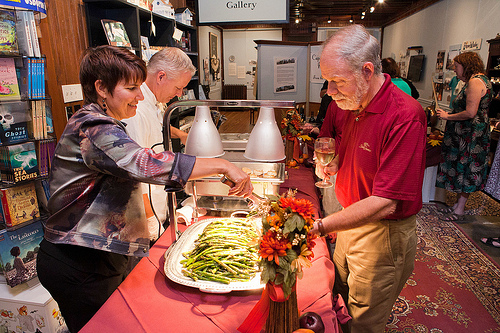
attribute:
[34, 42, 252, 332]
person — serving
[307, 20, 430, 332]
man — drinking, older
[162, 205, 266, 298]
plate — silver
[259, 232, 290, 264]
flower — orange, artificial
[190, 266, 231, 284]
asparagus — green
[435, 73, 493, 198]
dress — black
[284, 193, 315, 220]
flower — orange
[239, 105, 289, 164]
lamp — heated, silver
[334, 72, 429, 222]
shirt — red, collared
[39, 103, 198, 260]
jacket — printed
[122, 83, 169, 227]
shirt — white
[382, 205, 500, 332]
carpet — oriental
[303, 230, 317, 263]
flower — orange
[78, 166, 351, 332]
table cloth — red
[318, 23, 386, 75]
hair — thinning, grey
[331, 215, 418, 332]
pants — khaki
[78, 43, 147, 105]
hair — short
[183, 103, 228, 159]
lamp — heated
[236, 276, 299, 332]
bow — red